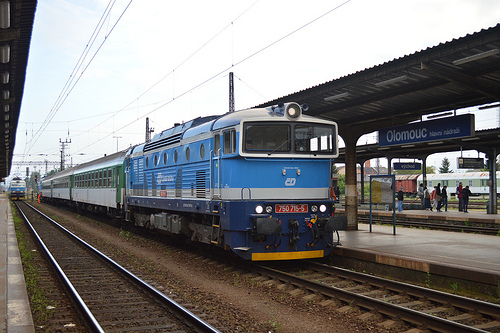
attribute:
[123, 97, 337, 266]
compartment — blue, first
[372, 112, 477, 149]
sign — blue, olomouc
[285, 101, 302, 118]
headlight — top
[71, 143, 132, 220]
car — green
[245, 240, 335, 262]
stripe — yellow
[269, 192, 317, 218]
plate — red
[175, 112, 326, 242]
car — first, blue and white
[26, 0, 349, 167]
cable — crossed, overhead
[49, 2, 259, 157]
cable — crossed, overhead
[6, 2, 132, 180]
cable — crossed, overhead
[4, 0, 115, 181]
cable — crossed, overhead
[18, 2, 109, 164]
cable — crossed, overhead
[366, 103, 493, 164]
sign — blue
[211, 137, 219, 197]
door — closed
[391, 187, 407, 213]
person — standing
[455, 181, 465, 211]
person — standing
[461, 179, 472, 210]
person — standing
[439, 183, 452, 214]
person — standing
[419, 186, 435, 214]
person — standing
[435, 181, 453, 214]
person — waiting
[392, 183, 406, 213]
person — waiting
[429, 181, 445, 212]
person — waiting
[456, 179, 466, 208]
person — waiting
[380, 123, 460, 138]
lettering — white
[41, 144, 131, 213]
cars — green, white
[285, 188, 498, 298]
platform — train